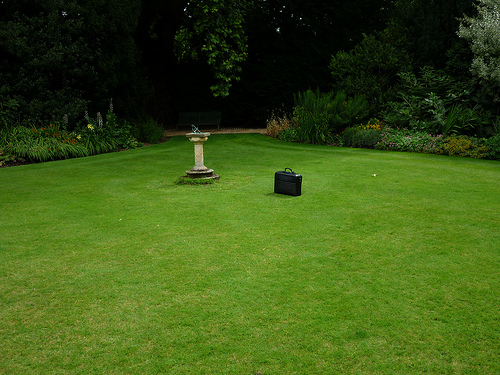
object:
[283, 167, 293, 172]
handle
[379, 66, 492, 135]
bush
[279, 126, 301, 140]
plants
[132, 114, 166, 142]
plants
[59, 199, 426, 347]
ground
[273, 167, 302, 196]
briefcase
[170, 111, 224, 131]
bench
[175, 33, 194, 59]
green leaves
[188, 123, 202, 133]
dial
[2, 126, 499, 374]
back yard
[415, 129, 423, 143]
leaves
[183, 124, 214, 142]
birdbath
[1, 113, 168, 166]
bush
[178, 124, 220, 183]
decoration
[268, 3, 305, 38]
sky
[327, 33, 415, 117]
trees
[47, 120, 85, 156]
plants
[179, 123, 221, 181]
sundial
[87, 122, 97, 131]
flower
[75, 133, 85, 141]
flower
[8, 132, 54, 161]
plant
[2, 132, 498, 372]
grass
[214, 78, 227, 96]
leaves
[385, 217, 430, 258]
patch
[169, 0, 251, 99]
tree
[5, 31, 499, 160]
background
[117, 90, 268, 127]
shade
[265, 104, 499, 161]
bush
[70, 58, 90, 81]
leaves